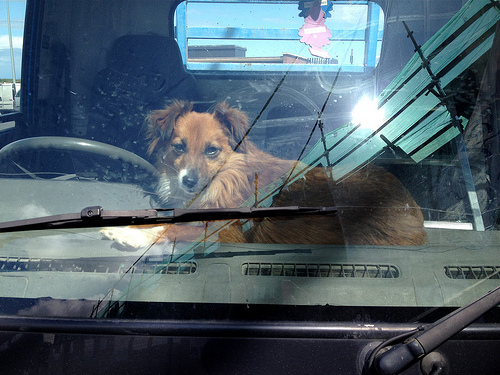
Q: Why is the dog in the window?
A: Relaxing.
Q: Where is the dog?
A: In the car.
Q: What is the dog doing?
A: Laying down.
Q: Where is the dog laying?
A: On the dashboard.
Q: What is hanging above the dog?
A: An air freshener.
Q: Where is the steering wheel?
A: To the right of the dog.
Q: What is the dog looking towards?
A: The camera.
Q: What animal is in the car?
A: A dog.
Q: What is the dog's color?
A: Brown and white.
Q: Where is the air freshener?
A: Above the dog.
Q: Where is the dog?
A: In a car.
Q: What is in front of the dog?
A: Windshield.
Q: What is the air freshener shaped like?
A: A tree.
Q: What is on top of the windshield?
A: Wipers.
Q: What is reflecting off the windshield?
A: Sunshine.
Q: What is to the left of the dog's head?
A: Steering wheel.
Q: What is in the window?
A: A dog.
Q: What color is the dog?
A: Brown.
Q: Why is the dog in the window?
A: Lying.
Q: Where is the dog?
A: The window.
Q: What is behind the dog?
A: A seat.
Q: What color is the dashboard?
A: Black.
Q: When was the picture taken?
A: Daytime.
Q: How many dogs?
A: 1.